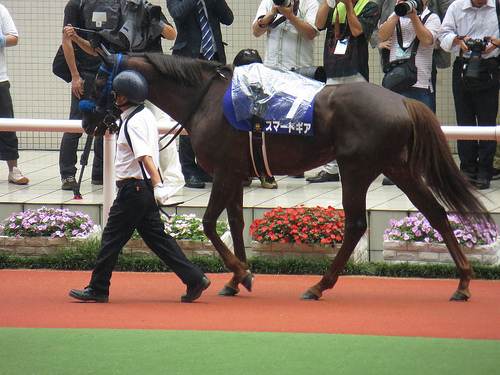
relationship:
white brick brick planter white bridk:
[6, 7, 283, 165] [3, 2, 421, 134]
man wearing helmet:
[69, 66, 213, 300] [109, 66, 148, 102]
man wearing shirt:
[69, 70, 210, 302] [102, 98, 167, 185]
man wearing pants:
[69, 66, 213, 300] [87, 174, 202, 293]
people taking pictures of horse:
[0, 1, 499, 201] [82, 40, 478, 300]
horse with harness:
[82, 40, 478, 300] [80, 52, 120, 124]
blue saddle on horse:
[230, 60, 319, 184] [82, 40, 478, 300]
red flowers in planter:
[244, 196, 344, 253] [248, 238, 368, 266]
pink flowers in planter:
[9, 211, 91, 249] [3, 224, 103, 254]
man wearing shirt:
[69, 66, 213, 300] [110, 103, 163, 179]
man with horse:
[69, 66, 213, 300] [82, 40, 478, 300]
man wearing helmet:
[69, 66, 213, 300] [112, 70, 151, 105]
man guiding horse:
[69, 70, 210, 302] [82, 40, 478, 300]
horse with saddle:
[82, 40, 478, 300] [218, 60, 324, 184]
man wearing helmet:
[69, 70, 210, 302] [110, 70, 150, 101]